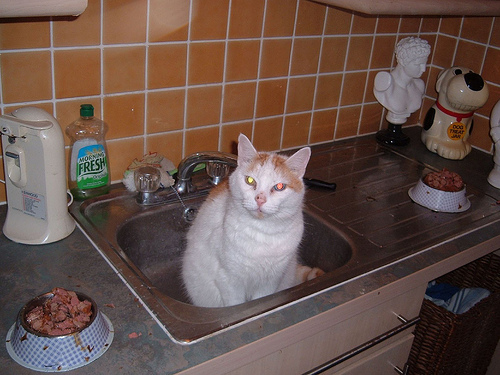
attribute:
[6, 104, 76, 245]
opener —  white,  electric,  for can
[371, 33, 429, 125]
statue —  white,  armless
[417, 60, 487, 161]
jar — for cookie,  dog shaped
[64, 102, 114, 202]
soap —  for dish,  meadow fresh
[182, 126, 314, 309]
kitty —  White and orange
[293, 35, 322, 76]
tiles —  Brown,  ceramic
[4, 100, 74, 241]
opener — for can,  Electric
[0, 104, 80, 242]
opener —  white,  electronic, for can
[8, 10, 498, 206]
wall —  orange,  tiled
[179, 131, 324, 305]
cat —  orange and white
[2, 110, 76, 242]
opener —  electric,  for can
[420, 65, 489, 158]
dog — for cookie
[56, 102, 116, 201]
meadow —  of dishsoap,  for soap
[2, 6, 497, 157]
tiles —  tiled